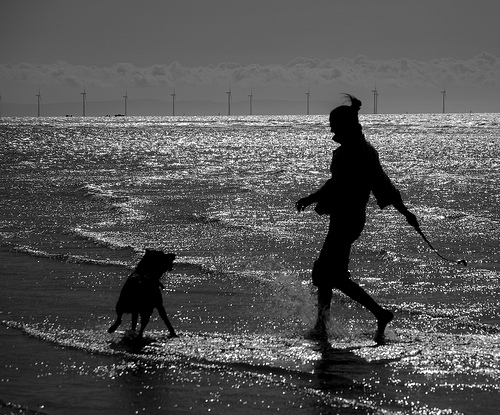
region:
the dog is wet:
[90, 222, 227, 397]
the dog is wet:
[67, 173, 268, 413]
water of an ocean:
[67, 133, 289, 217]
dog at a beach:
[98, 238, 192, 360]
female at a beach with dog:
[280, 64, 471, 362]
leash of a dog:
[412, 231, 473, 273]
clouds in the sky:
[33, 58, 388, 90]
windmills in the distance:
[221, 86, 243, 113]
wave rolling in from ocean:
[21, 328, 106, 357]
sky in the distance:
[42, 3, 444, 50]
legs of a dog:
[97, 318, 187, 342]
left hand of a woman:
[289, 194, 308, 218]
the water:
[230, 341, 280, 404]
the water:
[277, 347, 335, 412]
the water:
[213, 261, 261, 361]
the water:
[250, 290, 287, 404]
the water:
[199, 274, 273, 399]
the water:
[241, 317, 266, 381]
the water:
[244, 357, 271, 399]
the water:
[219, 243, 310, 367]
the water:
[221, 263, 246, 353]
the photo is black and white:
[11, 0, 499, 391]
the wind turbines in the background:
[21, 85, 480, 119]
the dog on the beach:
[83, 228, 207, 356]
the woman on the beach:
[285, 87, 464, 364]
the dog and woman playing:
[96, 82, 456, 360]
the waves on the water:
[58, 151, 143, 258]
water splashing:
[253, 259, 318, 332]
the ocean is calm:
[97, 130, 260, 190]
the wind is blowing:
[8, 4, 457, 412]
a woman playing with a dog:
[287, 94, 439, 351]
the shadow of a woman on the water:
[300, 330, 405, 408]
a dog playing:
[108, 241, 188, 335]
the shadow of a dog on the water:
[108, 327, 169, 375]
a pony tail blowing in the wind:
[340, 88, 370, 118]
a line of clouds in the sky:
[12, 52, 496, 85]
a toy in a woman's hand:
[408, 216, 473, 273]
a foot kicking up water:
[303, 310, 365, 350]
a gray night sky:
[2, 3, 494, 120]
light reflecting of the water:
[18, 118, 495, 164]